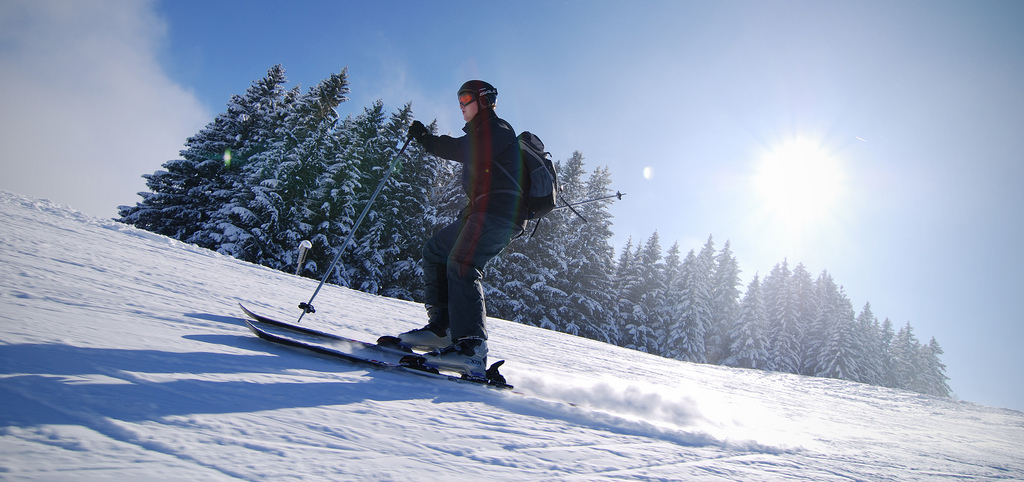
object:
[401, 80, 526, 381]
man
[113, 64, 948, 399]
trees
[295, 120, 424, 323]
poles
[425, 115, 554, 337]
gear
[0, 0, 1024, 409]
sky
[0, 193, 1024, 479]
snow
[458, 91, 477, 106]
goggles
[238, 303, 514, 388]
skis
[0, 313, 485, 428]
shadow